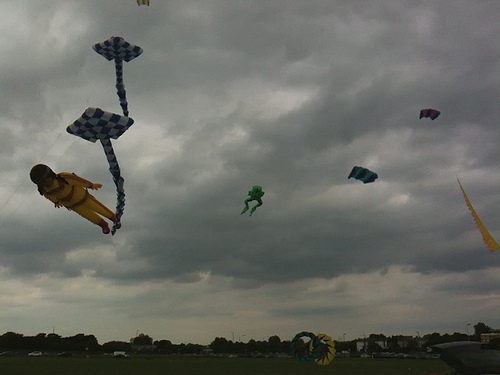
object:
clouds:
[111, 112, 479, 297]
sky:
[0, 2, 499, 322]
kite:
[85, 33, 152, 114]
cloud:
[262, 289, 375, 316]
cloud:
[5, 219, 120, 289]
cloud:
[334, 10, 475, 94]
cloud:
[204, 28, 365, 163]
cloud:
[415, 183, 497, 271]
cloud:
[125, 68, 497, 286]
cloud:
[91, 3, 496, 81]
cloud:
[1, 191, 112, 282]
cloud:
[2, 1, 100, 128]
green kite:
[240, 183, 269, 219]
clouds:
[214, 23, 270, 98]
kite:
[343, 162, 379, 187]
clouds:
[154, 52, 328, 157]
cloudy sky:
[2, 2, 498, 340]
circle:
[308, 331, 336, 365]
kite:
[449, 168, 499, 257]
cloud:
[239, 70, 330, 127]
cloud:
[122, 115, 193, 166]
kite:
[413, 103, 440, 127]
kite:
[24, 163, 121, 237]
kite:
[90, 33, 143, 115]